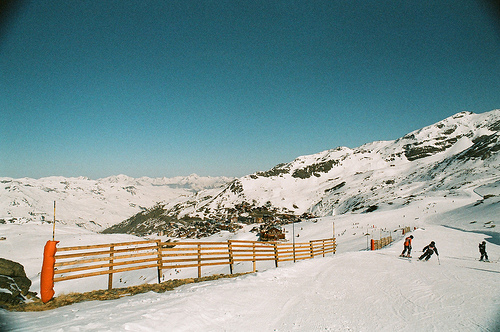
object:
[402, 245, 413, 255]
pant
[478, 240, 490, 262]
person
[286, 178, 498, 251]
trails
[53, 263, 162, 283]
slats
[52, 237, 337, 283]
fence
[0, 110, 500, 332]
snow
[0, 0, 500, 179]
blue sky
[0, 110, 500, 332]
land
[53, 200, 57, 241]
pole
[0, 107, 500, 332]
ground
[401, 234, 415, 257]
people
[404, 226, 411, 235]
fence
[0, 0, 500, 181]
sky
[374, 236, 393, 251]
fence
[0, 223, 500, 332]
skiing slope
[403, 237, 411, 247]
jacket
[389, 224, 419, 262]
skier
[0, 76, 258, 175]
light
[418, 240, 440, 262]
person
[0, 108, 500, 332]
hill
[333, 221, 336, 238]
pole